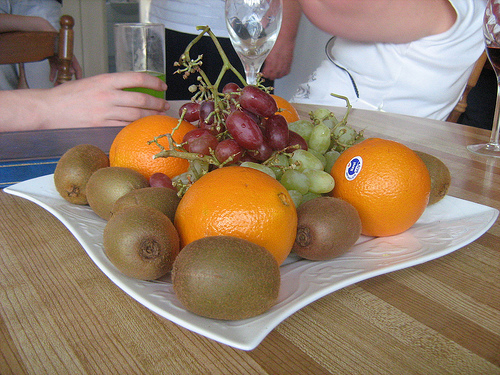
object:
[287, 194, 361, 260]
kiwi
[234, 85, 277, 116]
grape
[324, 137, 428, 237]
orange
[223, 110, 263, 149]
grape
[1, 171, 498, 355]
plate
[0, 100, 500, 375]
table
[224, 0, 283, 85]
glass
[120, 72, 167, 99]
liquid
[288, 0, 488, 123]
shirt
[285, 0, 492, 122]
person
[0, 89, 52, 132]
arm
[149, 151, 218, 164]
stem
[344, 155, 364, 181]
tag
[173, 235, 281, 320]
fruits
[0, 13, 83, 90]
chair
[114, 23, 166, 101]
glass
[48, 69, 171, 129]
hand